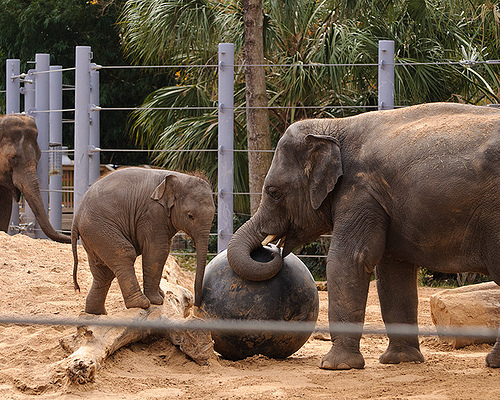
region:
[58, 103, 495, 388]
two elephants playing with a ball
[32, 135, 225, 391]
elephant standing on driftwood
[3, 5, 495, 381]
one elephant watches from a distance as the other two play with a ball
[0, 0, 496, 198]
palm trees in background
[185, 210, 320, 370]
dirt on black ball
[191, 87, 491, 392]
elephant with mouth open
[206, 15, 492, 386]
elephant with trunk curled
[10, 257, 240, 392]
driftwood in dirt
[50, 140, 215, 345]
elephant tail pointing down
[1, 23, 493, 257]
metal fencing enclosing the elephant habitat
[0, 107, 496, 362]
Three elephants behind a wire fence.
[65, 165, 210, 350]
A young calf standing on a wooden log.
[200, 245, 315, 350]
Elephant's trunk leaning on a large black ball.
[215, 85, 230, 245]
A metal fence post.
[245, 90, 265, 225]
A tree on the other side of the fence.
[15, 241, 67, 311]
Dirt on the ground.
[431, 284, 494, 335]
A log on the ground near an elephant.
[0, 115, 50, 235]
An elephant by the metal fence.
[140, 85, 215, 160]
Palm leaves on the other side of the fence.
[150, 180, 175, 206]
The calf's ear is folded over.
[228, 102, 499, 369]
Big elephant in a zoo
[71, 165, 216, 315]
Baby elephant in a zoo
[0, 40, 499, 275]
Fence around the elephant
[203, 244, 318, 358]
Big ball between the elephants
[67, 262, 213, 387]
A log under the baby elephant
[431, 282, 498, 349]
Rock behind the big elephant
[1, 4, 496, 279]
Trees outside of the fence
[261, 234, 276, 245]
Tusk of the big elephant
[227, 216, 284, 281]
Trunk of the big elephant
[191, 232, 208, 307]
Trunk of the baby elephant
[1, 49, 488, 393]
elephants in zoo exhibit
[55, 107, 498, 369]
baby elephant and adult elephant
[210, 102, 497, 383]
elephant playing with giant ball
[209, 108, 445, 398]
elephant pushing ball with trunk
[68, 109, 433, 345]
two elephants playing with giant ball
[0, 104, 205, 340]
old elephant behind baby elephant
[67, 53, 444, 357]
elephants behind fence at zoo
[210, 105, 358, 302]
trunk and ear of elephant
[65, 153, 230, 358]
baby elephant stepping on broken trunk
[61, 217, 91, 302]
tail of baby elephant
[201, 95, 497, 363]
elephant playing with a ball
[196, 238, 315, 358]
large dirty black ball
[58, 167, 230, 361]
baby elephant standing on wood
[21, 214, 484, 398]
sandy dirt ground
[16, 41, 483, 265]
metal fence with thick posts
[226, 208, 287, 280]
elephant trunk wrapped in a circle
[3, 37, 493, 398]
three caged elephants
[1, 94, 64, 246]
elephant with a long trunk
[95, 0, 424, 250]
palm trees behind the fence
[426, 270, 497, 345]
large log beside the elephant